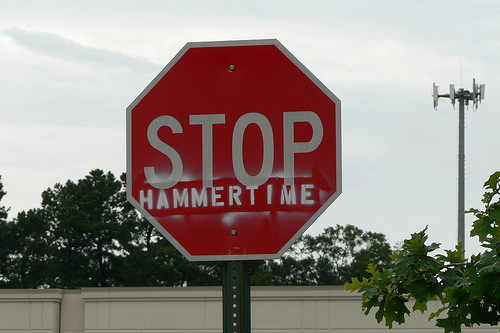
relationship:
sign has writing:
[124, 37, 344, 267] [136, 179, 317, 210]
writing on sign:
[136, 179, 317, 210] [124, 37, 344, 267]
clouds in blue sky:
[1, 6, 499, 222] [345, 87, 435, 154]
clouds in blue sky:
[1, 6, 499, 222] [340, 95, 430, 165]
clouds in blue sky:
[1, 6, 499, 222] [330, 0, 485, 50]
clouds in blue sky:
[1, 6, 499, 222] [0, 71, 120, 128]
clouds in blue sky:
[1, 6, 499, 222] [2, 77, 121, 118]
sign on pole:
[124, 37, 344, 267] [218, 258, 251, 331]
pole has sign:
[218, 258, 251, 331] [124, 37, 344, 267]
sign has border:
[124, 37, 344, 267] [182, 38, 276, 47]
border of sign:
[182, 38, 276, 47] [124, 37, 344, 267]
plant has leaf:
[347, 170, 484, 330] [348, 273, 368, 293]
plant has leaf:
[347, 170, 484, 330] [412, 296, 431, 311]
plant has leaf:
[347, 170, 484, 330] [445, 243, 468, 268]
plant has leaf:
[347, 170, 484, 330] [424, 305, 447, 320]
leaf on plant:
[348, 273, 368, 293] [347, 170, 484, 330]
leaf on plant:
[412, 296, 431, 311] [347, 170, 484, 330]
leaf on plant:
[445, 243, 468, 268] [347, 170, 484, 330]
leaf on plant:
[424, 305, 447, 320] [347, 170, 484, 330]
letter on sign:
[142, 114, 184, 190] [124, 37, 344, 267]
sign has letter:
[124, 37, 344, 267] [142, 114, 184, 190]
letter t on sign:
[190, 112, 227, 189] [124, 37, 344, 267]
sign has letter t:
[124, 37, 344, 267] [190, 112, 227, 189]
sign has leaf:
[124, 37, 344, 267] [437, 241, 467, 264]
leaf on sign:
[437, 241, 467, 264] [124, 37, 344, 267]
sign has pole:
[124, 37, 344, 267] [218, 258, 251, 331]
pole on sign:
[218, 258, 251, 331] [124, 37, 344, 267]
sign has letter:
[124, 37, 344, 267] [231, 111, 275, 189]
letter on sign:
[231, 111, 275, 189] [124, 37, 344, 267]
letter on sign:
[280, 109, 325, 186] [124, 37, 344, 267]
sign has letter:
[124, 37, 344, 267] [280, 109, 325, 186]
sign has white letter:
[124, 37, 344, 267] [138, 190, 154, 210]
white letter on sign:
[138, 190, 154, 210] [124, 37, 344, 267]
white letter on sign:
[156, 185, 167, 208] [124, 37, 344, 267]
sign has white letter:
[124, 37, 344, 267] [156, 185, 167, 208]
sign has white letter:
[124, 37, 344, 267] [172, 186, 189, 208]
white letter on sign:
[172, 186, 189, 208] [124, 37, 344, 267]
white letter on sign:
[190, 189, 210, 207] [124, 37, 344, 267]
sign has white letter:
[124, 37, 344, 267] [190, 189, 210, 207]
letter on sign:
[184, 182, 211, 211] [124, 37, 344, 267]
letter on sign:
[226, 182, 248, 208] [124, 37, 344, 267]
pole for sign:
[218, 258, 251, 331] [124, 37, 344, 267]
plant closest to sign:
[347, 168, 500, 333] [118, 36, 345, 331]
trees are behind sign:
[0, 168, 400, 286] [118, 36, 345, 331]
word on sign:
[141, 111, 321, 193] [124, 37, 344, 267]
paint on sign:
[134, 181, 320, 216] [124, 37, 344, 267]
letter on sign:
[137, 114, 187, 190] [124, 37, 344, 267]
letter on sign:
[228, 103, 277, 194] [124, 37, 344, 267]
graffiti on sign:
[141, 168, 328, 228] [124, 37, 344, 267]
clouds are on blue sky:
[1, 6, 499, 222] [332, 2, 482, 48]